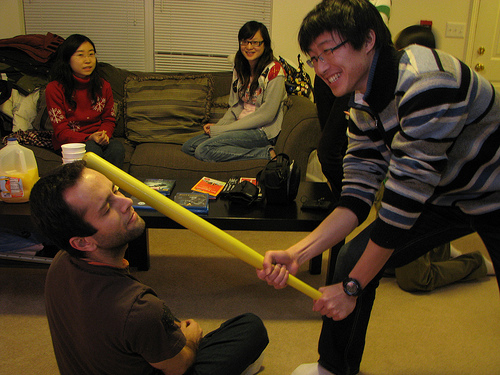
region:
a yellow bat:
[80, 144, 340, 316]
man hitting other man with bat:
[27, 5, 487, 371]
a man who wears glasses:
[295, 1, 394, 100]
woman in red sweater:
[40, 30, 122, 147]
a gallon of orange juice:
[0, 133, 41, 206]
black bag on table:
[257, 142, 304, 211]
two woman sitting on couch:
[7, 17, 322, 178]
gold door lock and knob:
[474, 40, 489, 71]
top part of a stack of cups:
[59, 136, 88, 163]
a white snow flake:
[45, 103, 67, 127]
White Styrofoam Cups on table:
[61, 140, 85, 165]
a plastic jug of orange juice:
[0, 140, 36, 200]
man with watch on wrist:
[333, 272, 371, 304]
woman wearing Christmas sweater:
[42, 35, 118, 146]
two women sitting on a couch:
[44, 32, 282, 163]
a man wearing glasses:
[298, 0, 385, 107]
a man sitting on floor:
[32, 167, 269, 371]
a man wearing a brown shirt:
[27, 164, 193, 374]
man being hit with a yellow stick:
[28, 164, 325, 374]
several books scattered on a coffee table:
[128, 162, 257, 218]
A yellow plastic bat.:
[76, 150, 342, 314]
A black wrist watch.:
[340, 272, 365, 300]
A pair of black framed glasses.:
[288, 37, 352, 74]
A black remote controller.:
[221, 169, 239, 196]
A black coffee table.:
[4, 162, 338, 277]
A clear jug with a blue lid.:
[1, 137, 40, 207]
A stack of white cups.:
[61, 142, 89, 162]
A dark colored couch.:
[13, 60, 321, 211]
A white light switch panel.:
[442, 22, 467, 38]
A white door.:
[461, 1, 498, 93]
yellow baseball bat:
[81, 145, 338, 299]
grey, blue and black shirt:
[321, 89, 493, 131]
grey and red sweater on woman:
[227, 72, 282, 126]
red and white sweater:
[49, 80, 151, 167]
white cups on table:
[59, 134, 88, 178]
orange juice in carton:
[4, 137, 46, 200]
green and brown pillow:
[132, 60, 212, 155]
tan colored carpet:
[402, 309, 495, 364]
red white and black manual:
[184, 170, 241, 201]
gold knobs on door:
[476, 41, 498, 86]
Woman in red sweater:
[45, 30, 120, 143]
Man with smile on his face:
[292, 1, 382, 98]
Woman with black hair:
[227, 18, 278, 103]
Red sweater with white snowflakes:
[40, 70, 121, 145]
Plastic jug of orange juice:
[1, 135, 39, 202]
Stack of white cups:
[61, 139, 86, 161]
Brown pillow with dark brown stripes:
[121, 70, 214, 145]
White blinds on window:
[155, 4, 230, 69]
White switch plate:
[442, 20, 467, 40]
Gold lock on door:
[476, 45, 486, 57]